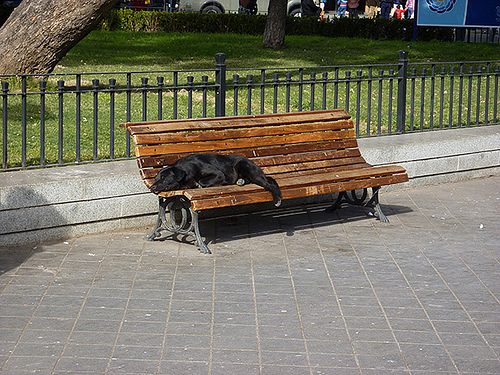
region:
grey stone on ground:
[106, 357, 158, 373]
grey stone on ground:
[57, 353, 109, 370]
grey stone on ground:
[306, 353, 358, 367]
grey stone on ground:
[257, 310, 301, 326]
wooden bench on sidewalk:
[113, 99, 417, 263]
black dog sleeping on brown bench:
[144, 146, 287, 212]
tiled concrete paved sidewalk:
[1, 164, 498, 374]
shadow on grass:
[1, 89, 61, 131]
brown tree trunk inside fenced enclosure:
[251, 0, 293, 55]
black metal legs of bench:
[140, 193, 215, 258]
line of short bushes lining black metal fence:
[98, 3, 458, 47]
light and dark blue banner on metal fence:
[409, 1, 499, 35]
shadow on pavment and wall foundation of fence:
[1, 179, 78, 289]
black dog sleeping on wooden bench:
[132, 109, 292, 210]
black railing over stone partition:
[6, 61, 494, 248]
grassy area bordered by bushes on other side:
[3, 12, 494, 166]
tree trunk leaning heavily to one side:
[4, 4, 111, 94]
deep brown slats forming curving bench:
[121, 108, 409, 217]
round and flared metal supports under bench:
[143, 185, 388, 252]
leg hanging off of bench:
[148, 150, 281, 213]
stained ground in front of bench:
[146, 188, 412, 269]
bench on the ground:
[91, 85, 412, 243]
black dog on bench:
[126, 141, 286, 228]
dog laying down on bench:
[125, 102, 354, 239]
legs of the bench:
[123, 192, 216, 254]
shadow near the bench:
[8, 186, 100, 285]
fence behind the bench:
[11, 53, 196, 145]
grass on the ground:
[88, 33, 228, 81]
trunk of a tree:
[243, 1, 309, 51]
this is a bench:
[88, 76, 443, 251]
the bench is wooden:
[103, 54, 438, 245]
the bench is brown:
[117, 94, 413, 254]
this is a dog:
[140, 134, 305, 211]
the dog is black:
[136, 126, 300, 218]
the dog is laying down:
[123, 72, 408, 262]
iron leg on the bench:
[143, 189, 225, 259]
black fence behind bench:
[5, 32, 492, 189]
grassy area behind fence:
[12, 18, 497, 174]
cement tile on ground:
[15, 165, 499, 370]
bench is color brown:
[113, 103, 419, 253]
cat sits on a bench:
[110, 100, 415, 259]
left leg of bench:
[146, 190, 211, 256]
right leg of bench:
[334, 185, 394, 225]